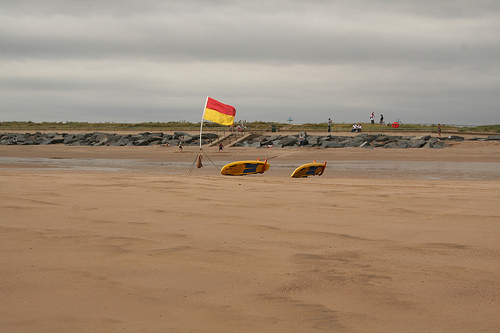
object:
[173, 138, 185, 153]
person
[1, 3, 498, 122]
sky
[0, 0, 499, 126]
clouds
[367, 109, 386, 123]
couple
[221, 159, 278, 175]
yellow raft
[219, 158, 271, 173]
surfboard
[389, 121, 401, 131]
kite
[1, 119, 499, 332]
ground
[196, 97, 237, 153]
flag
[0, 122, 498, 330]
sand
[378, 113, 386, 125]
person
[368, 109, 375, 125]
person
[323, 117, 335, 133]
person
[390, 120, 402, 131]
cloth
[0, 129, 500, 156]
rocks